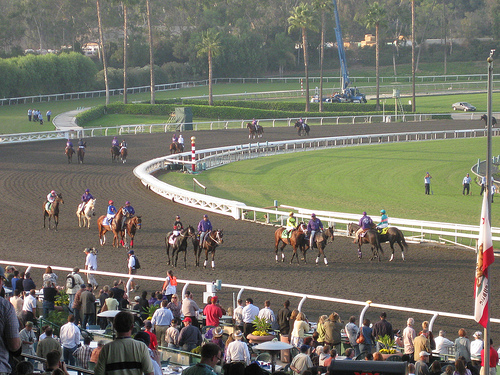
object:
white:
[481, 233, 491, 240]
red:
[482, 246, 495, 280]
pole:
[485, 59, 492, 226]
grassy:
[298, 161, 361, 207]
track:
[5, 162, 133, 191]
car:
[452, 102, 477, 112]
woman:
[161, 269, 177, 295]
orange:
[172, 277, 175, 285]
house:
[82, 41, 102, 52]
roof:
[82, 42, 98, 47]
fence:
[0, 73, 500, 107]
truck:
[325, 89, 367, 104]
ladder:
[334, 0, 352, 90]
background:
[0, 0, 500, 375]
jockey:
[42, 189, 65, 232]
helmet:
[50, 190, 55, 195]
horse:
[274, 221, 309, 266]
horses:
[42, 190, 64, 232]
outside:
[0, 0, 500, 138]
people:
[307, 213, 324, 251]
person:
[172, 214, 184, 248]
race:
[43, 189, 409, 270]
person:
[123, 201, 136, 217]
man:
[258, 300, 276, 334]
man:
[242, 298, 260, 342]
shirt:
[241, 304, 259, 324]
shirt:
[197, 219, 212, 232]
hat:
[83, 247, 91, 252]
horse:
[76, 198, 97, 229]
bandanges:
[275, 255, 279, 261]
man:
[126, 249, 141, 292]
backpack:
[133, 256, 140, 270]